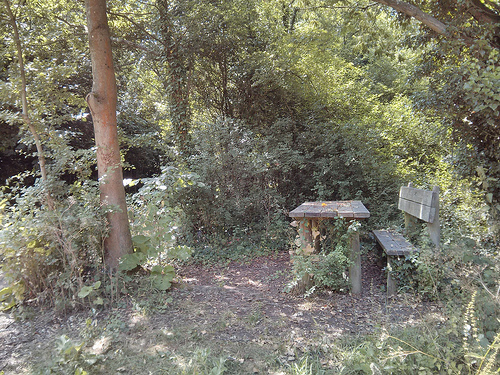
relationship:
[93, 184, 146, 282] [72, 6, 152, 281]
trunk of tree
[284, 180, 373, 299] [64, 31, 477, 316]
table in woods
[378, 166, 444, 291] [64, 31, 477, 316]
bench in woods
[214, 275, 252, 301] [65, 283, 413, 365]
dirt on ground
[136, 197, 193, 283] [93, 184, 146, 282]
weeds by trunk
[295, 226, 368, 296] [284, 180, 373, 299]
legs of table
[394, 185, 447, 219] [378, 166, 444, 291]
back of bench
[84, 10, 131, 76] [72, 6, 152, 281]
stem of tree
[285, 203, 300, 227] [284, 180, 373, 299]
edge of table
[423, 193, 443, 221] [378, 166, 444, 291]
edge of bench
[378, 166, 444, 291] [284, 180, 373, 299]
bench by table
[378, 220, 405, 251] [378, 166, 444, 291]
leaves on bench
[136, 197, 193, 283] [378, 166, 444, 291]
weeds by bench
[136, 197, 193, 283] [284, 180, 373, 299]
weeds by table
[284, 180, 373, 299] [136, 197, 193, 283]
table surrounded by weeds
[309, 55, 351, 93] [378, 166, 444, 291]
leaves on bench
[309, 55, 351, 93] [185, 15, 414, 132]
leaves on trees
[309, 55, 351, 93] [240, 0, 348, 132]
leaves on plant